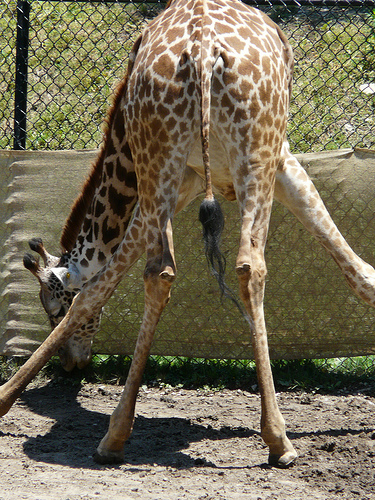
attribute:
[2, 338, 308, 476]
feet — spayed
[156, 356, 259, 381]
grass — green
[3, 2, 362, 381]
fence — chain link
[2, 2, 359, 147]
fence — metal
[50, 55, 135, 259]
mane — orange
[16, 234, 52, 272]
horns — small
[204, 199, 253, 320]
hair — long, black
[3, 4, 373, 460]
animal — large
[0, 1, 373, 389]
slope — grassy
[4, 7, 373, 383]
area — grassy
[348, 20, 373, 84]
bush — small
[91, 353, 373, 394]
grass — green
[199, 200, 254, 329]
bush — black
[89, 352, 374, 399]
grass — green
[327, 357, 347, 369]
object — white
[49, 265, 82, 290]
ear — long, white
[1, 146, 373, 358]
covering — tan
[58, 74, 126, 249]
mane — brown